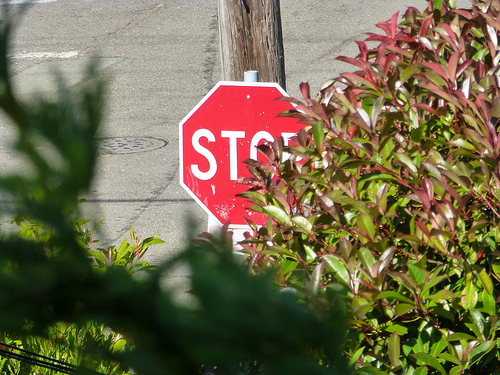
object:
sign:
[177, 80, 326, 228]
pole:
[217, 2, 286, 88]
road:
[2, 0, 476, 310]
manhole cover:
[98, 135, 169, 155]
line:
[9, 49, 77, 61]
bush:
[241, 0, 499, 374]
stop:
[190, 127, 299, 181]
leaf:
[358, 171, 393, 193]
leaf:
[337, 56, 376, 76]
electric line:
[2, 342, 99, 374]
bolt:
[247, 94, 251, 99]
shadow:
[0, 198, 192, 203]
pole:
[244, 69, 259, 85]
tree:
[0, 62, 90, 375]